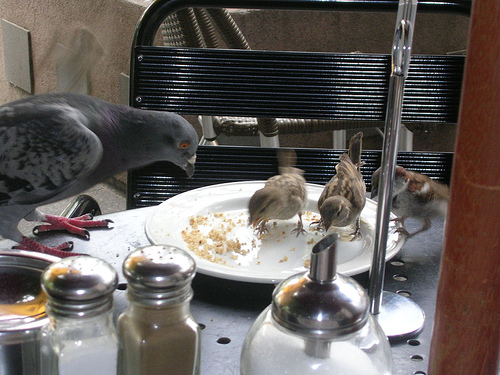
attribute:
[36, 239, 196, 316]
lids — silver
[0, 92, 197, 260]
bird — Brown, grey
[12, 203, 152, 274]
toes — red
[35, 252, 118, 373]
shaker — salt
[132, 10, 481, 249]
chair — black, metal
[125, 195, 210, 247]
plate — white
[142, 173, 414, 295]
plate — white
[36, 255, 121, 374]
bottle — Clear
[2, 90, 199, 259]
pigeon — big, grey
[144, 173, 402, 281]
plate — empty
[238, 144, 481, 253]
birds — brown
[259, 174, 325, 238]
bird — Brown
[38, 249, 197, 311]
lids — silver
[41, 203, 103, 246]
foot — pink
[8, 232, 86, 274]
foot — pink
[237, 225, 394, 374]
bottle — Clear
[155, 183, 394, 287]
plate — white